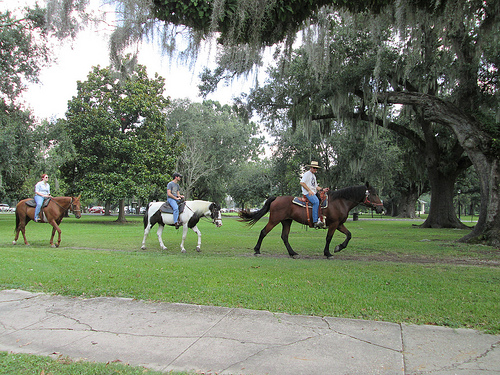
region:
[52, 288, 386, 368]
A wide concrete sidewalk.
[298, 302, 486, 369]
Some cracks in the sidewalk.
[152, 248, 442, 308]
A section of green grass.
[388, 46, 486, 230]
Tree with large trunk.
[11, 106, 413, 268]
Three people riding horses.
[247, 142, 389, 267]
A man on a dark brown horse.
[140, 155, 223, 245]
Young man riding a horse.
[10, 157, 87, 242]
Woman riding a horse.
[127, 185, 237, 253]
A black and white horse.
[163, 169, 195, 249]
Young man wearing jeans.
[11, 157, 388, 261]
3 people riding horses.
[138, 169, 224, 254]
Man on a black and white paint horse.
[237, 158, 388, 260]
Man on a bay horse.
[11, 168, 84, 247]
Woman on a chestnut horse.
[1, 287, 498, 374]
Concrete sidewalk with cracks in it.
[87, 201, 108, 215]
Red car.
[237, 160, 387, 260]
Man in hat riding a horse.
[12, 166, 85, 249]
Woman in jeans riding a horse.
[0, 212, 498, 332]
Grassy area.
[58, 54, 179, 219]
Tall tree.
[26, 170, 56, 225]
A woman sitting on a horse.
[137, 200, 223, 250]
Black and white horse.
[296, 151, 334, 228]
A man with a hat.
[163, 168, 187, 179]
A black cap.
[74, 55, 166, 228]
A big tree.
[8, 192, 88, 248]
A brown horse.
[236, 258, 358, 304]
Green grass in the park.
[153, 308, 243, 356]
A cracked sidewalk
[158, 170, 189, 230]
A male with a blue pants.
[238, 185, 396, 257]
A horse walking.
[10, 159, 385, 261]
three people riding horses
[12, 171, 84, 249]
a woman riding on a brown horse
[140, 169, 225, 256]
a man riding on a black and white horse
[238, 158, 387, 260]
a man riding on a brown horse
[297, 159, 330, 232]
a man wearing a hat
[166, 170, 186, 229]
a man wearing a hat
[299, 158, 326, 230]
a man wearing sunglasses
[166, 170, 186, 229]
a man wearing blue jeans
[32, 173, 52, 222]
a woman wearing blue jeans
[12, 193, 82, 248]
a brown horse with a black saddle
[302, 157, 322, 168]
Wide-brimmed hat on man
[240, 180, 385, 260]
Dark brown horse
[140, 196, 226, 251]
Pinto horse walking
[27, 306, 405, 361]
Cracks in sidewalk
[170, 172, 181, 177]
Baseball cap on head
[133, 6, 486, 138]
Spanish moss growing in trees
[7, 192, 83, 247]
Red horse walking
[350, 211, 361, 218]
Trash can receptacle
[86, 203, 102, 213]
Red car parked in parking lot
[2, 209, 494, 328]
Green grass growing on ground